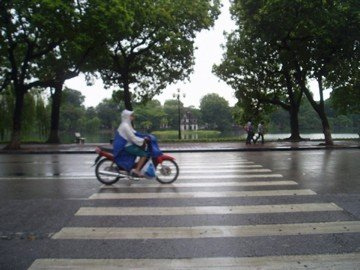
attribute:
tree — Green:
[218, 25, 310, 138]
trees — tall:
[226, 1, 357, 146]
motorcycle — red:
[88, 140, 187, 192]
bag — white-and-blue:
[144, 163, 156, 181]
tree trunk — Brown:
[284, 111, 304, 143]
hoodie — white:
[118, 109, 144, 146]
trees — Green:
[1, 1, 198, 146]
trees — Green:
[215, 1, 354, 141]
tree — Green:
[300, 0, 357, 148]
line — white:
[25, 255, 358, 268]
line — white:
[48, 220, 359, 240]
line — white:
[74, 202, 342, 215]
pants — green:
[125, 145, 148, 157]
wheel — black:
[148, 155, 193, 196]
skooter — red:
[94, 144, 179, 187]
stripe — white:
[77, 195, 349, 211]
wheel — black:
[94, 153, 120, 189]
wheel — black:
[152, 155, 181, 185]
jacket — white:
[117, 105, 133, 169]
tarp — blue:
[137, 129, 161, 159]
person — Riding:
[106, 105, 149, 171]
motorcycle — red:
[92, 132, 180, 188]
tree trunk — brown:
[47, 82, 68, 142]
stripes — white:
[82, 138, 340, 268]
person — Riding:
[109, 105, 147, 182]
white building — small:
[178, 113, 207, 133]